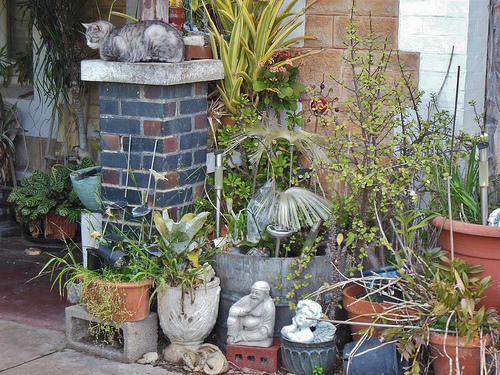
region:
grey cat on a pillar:
[80, 8, 194, 63]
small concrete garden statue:
[217, 275, 282, 350]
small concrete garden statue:
[277, 296, 339, 348]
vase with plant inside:
[148, 204, 228, 366]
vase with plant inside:
[24, 231, 156, 323]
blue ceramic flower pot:
[67, 157, 104, 211]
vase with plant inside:
[3, 162, 83, 240]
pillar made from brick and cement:
[64, 53, 230, 265]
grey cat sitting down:
[77, 12, 188, 64]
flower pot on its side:
[340, 327, 423, 374]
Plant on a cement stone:
[65, 258, 161, 335]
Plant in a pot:
[132, 238, 224, 349]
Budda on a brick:
[230, 280, 299, 374]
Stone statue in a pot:
[278, 288, 337, 359]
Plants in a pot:
[211, 100, 353, 267]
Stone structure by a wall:
[76, 46, 216, 236]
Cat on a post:
[78, 10, 205, 70]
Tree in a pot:
[333, 93, 449, 318]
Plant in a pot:
[21, 148, 106, 226]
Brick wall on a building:
[285, 6, 497, 102]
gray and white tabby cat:
[81, 19, 198, 106]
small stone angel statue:
[275, 301, 341, 356]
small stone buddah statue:
[227, 273, 278, 360]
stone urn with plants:
[151, 211, 218, 374]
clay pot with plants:
[60, 238, 152, 323]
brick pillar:
[81, 57, 227, 233]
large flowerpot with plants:
[397, 81, 499, 321]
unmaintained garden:
[6, 21, 499, 373]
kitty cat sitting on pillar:
[75, 17, 207, 87]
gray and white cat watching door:
[67, 11, 222, 101]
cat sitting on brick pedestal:
[78, 16, 195, 68]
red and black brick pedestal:
[76, 50, 248, 353]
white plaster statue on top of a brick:
[225, 274, 275, 354]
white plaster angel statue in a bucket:
[279, 297, 339, 351]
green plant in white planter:
[143, 199, 226, 374]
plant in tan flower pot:
[83, 228, 160, 327]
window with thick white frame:
[0, 0, 72, 143]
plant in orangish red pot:
[355, 238, 497, 373]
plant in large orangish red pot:
[405, 61, 498, 353]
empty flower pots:
[333, 264, 440, 374]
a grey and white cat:
[76, 16, 189, 70]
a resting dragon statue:
[173, 341, 230, 373]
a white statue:
[226, 278, 274, 351]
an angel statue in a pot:
[281, 294, 335, 373]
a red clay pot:
[419, 324, 489, 371]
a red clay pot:
[338, 279, 437, 335]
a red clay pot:
[428, 209, 496, 326]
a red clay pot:
[77, 269, 153, 326]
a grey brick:
[61, 301, 159, 365]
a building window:
[1, 2, 39, 104]